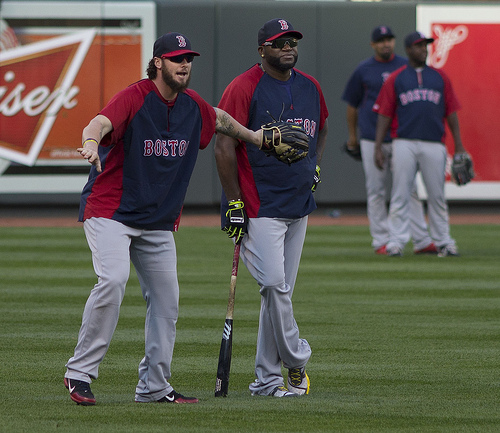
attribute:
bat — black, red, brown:
[212, 226, 243, 398]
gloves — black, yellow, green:
[219, 201, 252, 243]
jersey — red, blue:
[91, 77, 217, 232]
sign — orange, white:
[0, 1, 157, 191]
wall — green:
[0, 1, 499, 204]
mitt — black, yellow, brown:
[254, 125, 310, 166]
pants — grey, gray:
[66, 214, 187, 399]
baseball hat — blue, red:
[148, 32, 199, 65]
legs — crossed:
[235, 224, 314, 374]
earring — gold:
[260, 50, 264, 59]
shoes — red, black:
[62, 367, 199, 405]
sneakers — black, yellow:
[248, 367, 319, 407]